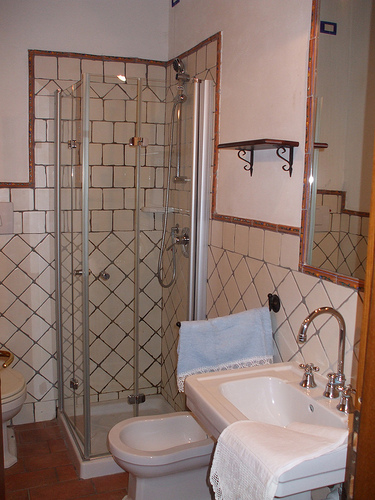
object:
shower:
[57, 56, 213, 480]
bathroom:
[1, 1, 374, 500]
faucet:
[295, 306, 346, 397]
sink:
[183, 361, 348, 498]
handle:
[299, 362, 320, 389]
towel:
[209, 419, 349, 500]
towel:
[176, 308, 274, 394]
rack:
[176, 294, 281, 329]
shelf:
[216, 138, 299, 178]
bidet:
[107, 410, 218, 500]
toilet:
[1, 351, 28, 469]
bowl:
[1, 386, 28, 420]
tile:
[248, 226, 265, 261]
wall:
[161, 1, 373, 409]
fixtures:
[296, 306, 357, 414]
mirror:
[299, 1, 375, 291]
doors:
[59, 79, 83, 451]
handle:
[336, 384, 357, 414]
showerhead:
[172, 57, 184, 73]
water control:
[165, 227, 190, 252]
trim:
[208, 473, 224, 500]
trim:
[176, 356, 273, 393]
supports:
[238, 145, 255, 177]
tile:
[210, 220, 223, 248]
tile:
[222, 221, 236, 254]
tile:
[234, 223, 248, 256]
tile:
[263, 229, 282, 266]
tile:
[280, 231, 300, 270]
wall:
[2, 1, 170, 425]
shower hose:
[157, 89, 178, 289]